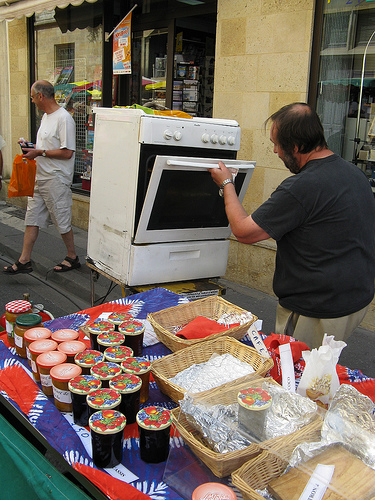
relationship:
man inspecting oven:
[206, 102, 372, 358] [86, 104, 257, 289]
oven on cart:
[86, 104, 257, 289] [83, 260, 226, 307]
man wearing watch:
[206, 102, 372, 358] [215, 178, 233, 197]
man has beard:
[206, 102, 372, 358] [276, 149, 302, 173]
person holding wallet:
[5, 79, 81, 274] [16, 137, 31, 154]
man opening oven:
[206, 102, 372, 358] [86, 104, 257, 289]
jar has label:
[48, 363, 82, 413] [52, 388, 72, 405]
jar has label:
[35, 351, 66, 398] [37, 373, 52, 387]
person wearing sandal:
[5, 79, 81, 274] [2, 260, 35, 274]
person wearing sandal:
[5, 79, 81, 274] [52, 255, 83, 275]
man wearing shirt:
[206, 102, 372, 358] [251, 152, 374, 319]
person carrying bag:
[5, 79, 81, 274] [4, 156, 39, 200]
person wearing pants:
[5, 79, 81, 274] [23, 171, 74, 237]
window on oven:
[147, 168, 247, 231] [86, 104, 257, 289]